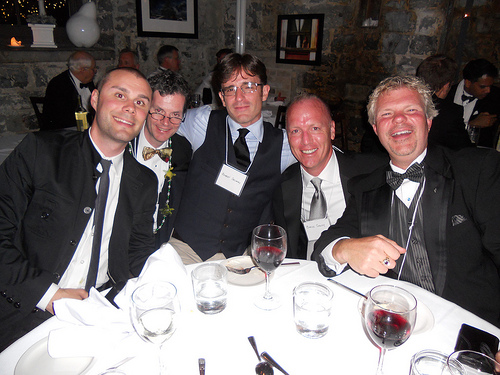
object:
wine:
[252, 246, 284, 272]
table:
[0, 247, 498, 373]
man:
[310, 74, 500, 329]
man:
[167, 53, 300, 265]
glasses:
[220, 82, 264, 97]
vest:
[173, 108, 284, 262]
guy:
[446, 58, 499, 150]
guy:
[38, 50, 97, 133]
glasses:
[148, 111, 187, 125]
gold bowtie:
[142, 146, 173, 163]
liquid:
[196, 293, 226, 315]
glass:
[190, 261, 226, 314]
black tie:
[84, 158, 113, 292]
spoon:
[247, 335, 289, 374]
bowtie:
[386, 161, 426, 190]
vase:
[65, 1, 100, 50]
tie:
[142, 146, 173, 163]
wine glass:
[190, 224, 334, 339]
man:
[347, 78, 498, 293]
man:
[270, 87, 390, 261]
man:
[0, 68, 158, 350]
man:
[142, 70, 187, 201]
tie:
[309, 177, 328, 221]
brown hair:
[211, 53, 268, 88]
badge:
[214, 163, 250, 198]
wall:
[333, 11, 363, 70]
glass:
[250, 223, 288, 300]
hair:
[366, 75, 440, 127]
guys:
[0, 44, 500, 338]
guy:
[129, 69, 195, 246]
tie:
[233, 128, 251, 172]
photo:
[275, 12, 322, 67]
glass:
[361, 285, 418, 369]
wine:
[367, 310, 412, 349]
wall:
[240, 0, 484, 130]